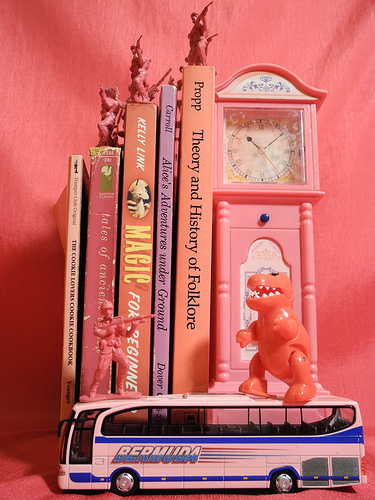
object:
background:
[1, 2, 375, 500]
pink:
[1, 1, 373, 498]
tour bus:
[46, 385, 368, 497]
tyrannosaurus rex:
[234, 266, 329, 408]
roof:
[68, 393, 359, 414]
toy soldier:
[182, 0, 221, 66]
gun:
[189, 2, 213, 34]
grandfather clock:
[204, 55, 334, 426]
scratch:
[239, 111, 247, 118]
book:
[170, 58, 216, 399]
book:
[152, 80, 178, 426]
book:
[111, 96, 159, 426]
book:
[77, 144, 120, 402]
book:
[52, 149, 88, 437]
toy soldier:
[125, 33, 172, 107]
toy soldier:
[97, 83, 127, 148]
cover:
[73, 141, 123, 456]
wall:
[2, 2, 374, 432]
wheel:
[105, 468, 144, 499]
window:
[98, 404, 150, 439]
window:
[147, 407, 171, 440]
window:
[169, 406, 207, 438]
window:
[204, 407, 262, 440]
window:
[259, 406, 287, 439]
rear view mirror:
[57, 419, 66, 437]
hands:
[239, 130, 292, 156]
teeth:
[243, 281, 284, 306]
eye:
[270, 271, 279, 276]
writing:
[109, 442, 204, 467]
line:
[92, 434, 368, 446]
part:
[114, 470, 137, 485]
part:
[204, 407, 224, 423]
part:
[83, 440, 97, 458]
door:
[67, 413, 95, 481]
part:
[158, 80, 180, 149]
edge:
[112, 479, 121, 494]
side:
[105, 144, 122, 435]